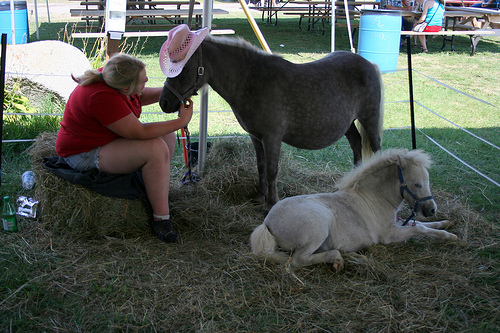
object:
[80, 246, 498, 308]
grass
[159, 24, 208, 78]
hat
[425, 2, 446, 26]
blue shirt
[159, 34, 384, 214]
animal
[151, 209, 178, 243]
foot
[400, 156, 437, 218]
head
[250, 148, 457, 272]
animal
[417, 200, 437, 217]
nose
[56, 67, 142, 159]
red shirt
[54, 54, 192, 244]
lady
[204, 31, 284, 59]
hair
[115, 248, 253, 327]
hay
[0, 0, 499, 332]
ground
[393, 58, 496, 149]
grass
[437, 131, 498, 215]
shadow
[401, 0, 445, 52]
woman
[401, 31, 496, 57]
bench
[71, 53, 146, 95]
hair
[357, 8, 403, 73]
trashcan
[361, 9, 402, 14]
bag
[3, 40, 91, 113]
boulder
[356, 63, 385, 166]
tail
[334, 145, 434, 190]
mane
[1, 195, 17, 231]
bottle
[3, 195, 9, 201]
top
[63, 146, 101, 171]
shorts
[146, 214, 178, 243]
shoes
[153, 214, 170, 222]
socks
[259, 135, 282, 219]
leg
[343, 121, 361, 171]
leg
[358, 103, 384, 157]
leg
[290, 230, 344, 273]
leg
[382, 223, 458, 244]
leg